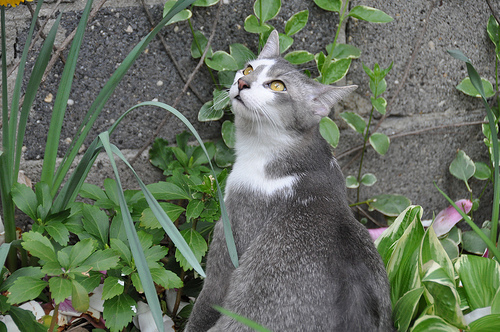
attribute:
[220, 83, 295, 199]
fur — white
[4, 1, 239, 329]
grasses — tall, green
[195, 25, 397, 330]
cat — gray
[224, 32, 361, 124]
face — white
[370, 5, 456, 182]
wall — gray, stone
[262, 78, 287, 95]
eye — golden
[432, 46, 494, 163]
leaves wall — green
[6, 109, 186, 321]
leaves wall — brick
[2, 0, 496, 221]
cinderblock — gray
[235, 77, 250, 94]
cat nose — small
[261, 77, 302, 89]
eyes — golden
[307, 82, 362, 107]
ear — cat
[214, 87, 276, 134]
whiskers — white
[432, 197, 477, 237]
bud — pink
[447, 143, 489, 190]
leaves — green and white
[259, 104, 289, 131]
whiskers — white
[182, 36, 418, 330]
cat — gray